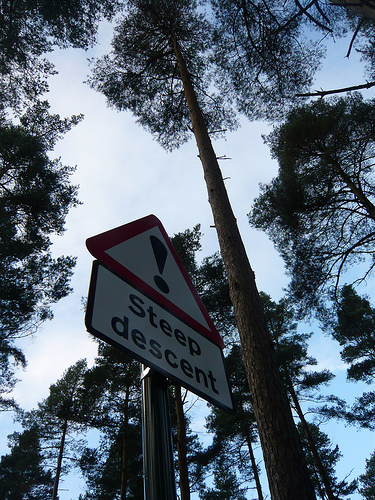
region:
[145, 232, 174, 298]
A large black exclamation point.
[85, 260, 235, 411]
A sign that says Steep Descent.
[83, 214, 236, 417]
A warning sign.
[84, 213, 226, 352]
A triangle with black, white, and red colors.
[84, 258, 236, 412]
A black and white rectangular sign.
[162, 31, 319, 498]
The trunk of a very tall tree.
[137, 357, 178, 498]
A metal sign pole.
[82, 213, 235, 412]
Two signs indicating danger.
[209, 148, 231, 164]
A branch poking out of a tree branch.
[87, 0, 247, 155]
The top of a large tree.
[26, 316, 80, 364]
The sky is clear and blue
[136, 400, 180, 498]
The pole is the color silver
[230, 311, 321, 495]
The tree trunk is the color brown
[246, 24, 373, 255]
The tree is tall with green leaves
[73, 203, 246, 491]
The sign is in the ground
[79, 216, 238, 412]
The top of the sign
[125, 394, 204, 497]
The bottom of the sign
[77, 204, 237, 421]
The sign is red, black and white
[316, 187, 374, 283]
The branches on the tree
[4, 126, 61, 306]
The leaves on the tree are short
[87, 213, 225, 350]
A red triangular sign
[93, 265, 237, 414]
A black and white rectangular sign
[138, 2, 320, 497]
A tall evergreen tree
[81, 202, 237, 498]
A metal post with two signs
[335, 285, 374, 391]
The top of an evergreen tree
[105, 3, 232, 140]
The branches of a tree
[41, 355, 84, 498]
A single evergreen tree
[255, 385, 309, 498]
The bark on the tree is brown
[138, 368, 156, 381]
A metal clasp holding the sign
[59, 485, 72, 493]
A branch on the tree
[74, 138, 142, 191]
sky above the trees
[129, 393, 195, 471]
bottom of the sign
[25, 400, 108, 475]
trees near the sign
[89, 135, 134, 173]
blue sky above the land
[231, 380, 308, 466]
branch of the tree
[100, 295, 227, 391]
black and white sign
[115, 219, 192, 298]
sign with an exclamation point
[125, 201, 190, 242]
tip of the sign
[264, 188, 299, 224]
leaves on a tall tree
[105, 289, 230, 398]
sign that says "steep descent"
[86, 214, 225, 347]
a red and white triangle sign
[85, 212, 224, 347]
a red and white warning sign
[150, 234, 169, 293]
a black exclamation point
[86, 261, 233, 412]
a sign warning about a steep descent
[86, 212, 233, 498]
two signs on a metal pole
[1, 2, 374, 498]
several very tall pine trees in a forest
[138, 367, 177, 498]
a shiny metal pole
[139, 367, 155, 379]
a metal bracket holding the sign to the pole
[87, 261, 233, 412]
a black and white sign with words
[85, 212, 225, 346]
a red and white sign with a punctuation mark